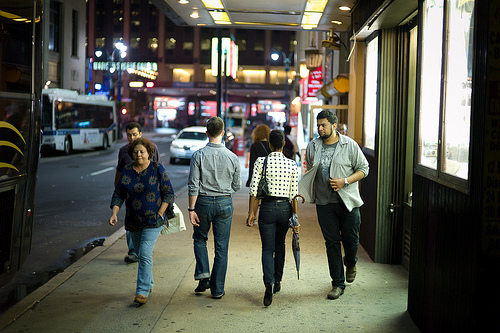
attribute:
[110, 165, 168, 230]
sweater — blue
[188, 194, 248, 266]
jeans — blue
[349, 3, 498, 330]
storefront — unknown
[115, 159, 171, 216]
shirt — blue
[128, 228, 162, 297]
jeans — light blue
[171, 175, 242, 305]
jeans — blue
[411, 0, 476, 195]
window — brightly lit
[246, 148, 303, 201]
shirt — white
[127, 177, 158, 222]
sweater — blue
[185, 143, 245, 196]
shirt — gray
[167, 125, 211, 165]
limousine — white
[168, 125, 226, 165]
vehicle — white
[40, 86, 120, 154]
tour bus — white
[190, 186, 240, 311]
jeans — blue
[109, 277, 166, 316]
shoes — brown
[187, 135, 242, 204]
shirt — blue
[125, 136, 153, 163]
hair — short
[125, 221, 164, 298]
jeans — blue